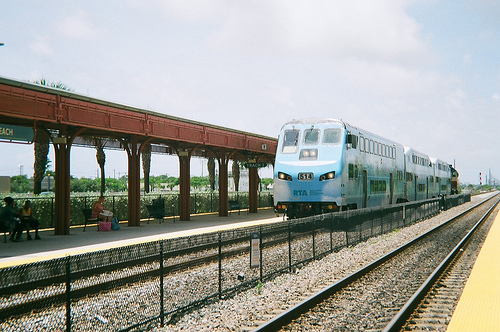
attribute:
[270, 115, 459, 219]
train — blue, long, white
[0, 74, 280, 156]
bridge — rust-colored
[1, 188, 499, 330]
gravel — gray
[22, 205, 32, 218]
shirt — orange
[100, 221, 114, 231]
bag — pink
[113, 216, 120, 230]
bag — blue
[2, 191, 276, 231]
fence — metal, chain-link, black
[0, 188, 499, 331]
track — red, silver, long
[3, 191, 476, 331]
fence — mesh, large, wire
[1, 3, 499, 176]
sky — clear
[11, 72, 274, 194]
trees — green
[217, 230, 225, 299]
post — black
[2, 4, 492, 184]
clouds — white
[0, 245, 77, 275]
paint — yellow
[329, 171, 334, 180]
light — yellow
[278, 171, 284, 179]
light — yellow